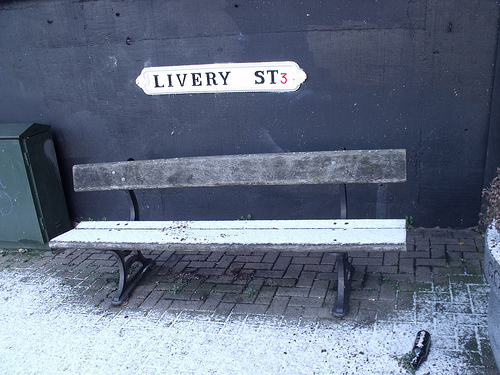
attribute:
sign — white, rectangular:
[134, 59, 308, 97]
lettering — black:
[150, 68, 233, 90]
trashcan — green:
[2, 119, 72, 244]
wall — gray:
[0, 2, 497, 240]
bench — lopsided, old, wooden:
[47, 144, 413, 317]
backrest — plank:
[66, 143, 413, 195]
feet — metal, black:
[106, 256, 357, 321]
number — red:
[278, 70, 290, 90]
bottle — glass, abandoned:
[409, 328, 431, 370]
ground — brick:
[0, 232, 483, 373]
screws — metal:
[331, 219, 351, 245]